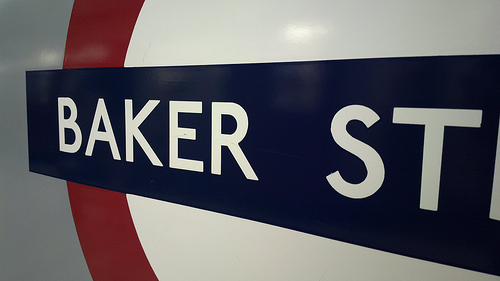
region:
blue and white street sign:
[6, 52, 498, 278]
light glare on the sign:
[281, 18, 321, 44]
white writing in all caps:
[46, 95, 260, 188]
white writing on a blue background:
[326, 95, 499, 222]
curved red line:
[45, 0, 196, 280]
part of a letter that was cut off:
[488, 107, 499, 232]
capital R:
[208, 99, 265, 186]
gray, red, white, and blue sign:
[0, 3, 499, 280]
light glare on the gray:
[31, 48, 61, 65]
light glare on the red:
[72, 45, 115, 60]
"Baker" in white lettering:
[52, 95, 253, 178]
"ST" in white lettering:
[326, 96, 482, 222]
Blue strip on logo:
[20, 50, 496, 270]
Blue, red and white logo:
[22, 3, 495, 278]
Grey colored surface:
[0, 0, 90, 280]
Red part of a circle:
[56, 0, 156, 275]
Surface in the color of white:
[122, 0, 494, 276]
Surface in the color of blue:
[21, 47, 496, 279]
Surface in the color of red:
[61, 0, 163, 280]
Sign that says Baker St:
[22, 40, 493, 271]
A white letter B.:
[53, 94, 84, 155]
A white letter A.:
[83, 95, 122, 160]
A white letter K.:
[123, 94, 164, 169]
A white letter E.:
[168, 98, 206, 174]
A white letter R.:
[210, 98, 258, 183]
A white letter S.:
[325, 103, 385, 202]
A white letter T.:
[391, 102, 484, 213]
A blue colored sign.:
[23, 55, 499, 275]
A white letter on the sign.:
[486, 118, 498, 223]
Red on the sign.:
[60, 0, 158, 280]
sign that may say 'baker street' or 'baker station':
[17, 49, 499, 274]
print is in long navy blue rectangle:
[19, 48, 499, 279]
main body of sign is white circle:
[115, 0, 499, 279]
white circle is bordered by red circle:
[53, 0, 499, 280]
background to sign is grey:
[2, 1, 111, 278]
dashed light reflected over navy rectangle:
[19, 18, 364, 71]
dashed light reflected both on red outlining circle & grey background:
[39, 24, 116, 69]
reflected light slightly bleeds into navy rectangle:
[34, 65, 341, 133]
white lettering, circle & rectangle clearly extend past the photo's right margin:
[24, 46, 497, 276]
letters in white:
[54, 88, 498, 207]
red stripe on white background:
[58, 187, 161, 277]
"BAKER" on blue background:
[44, 93, 263, 190]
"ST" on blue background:
[324, 82, 486, 218]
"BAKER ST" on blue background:
[47, 85, 486, 210]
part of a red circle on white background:
[49, 9, 159, 279]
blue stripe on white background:
[18, 51, 498, 226]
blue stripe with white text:
[22, 54, 497, 254]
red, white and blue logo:
[17, 14, 495, 279]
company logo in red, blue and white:
[9, 8, 485, 279]